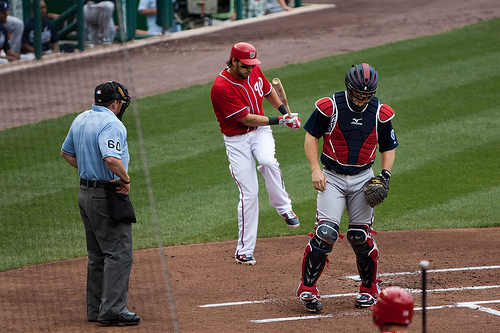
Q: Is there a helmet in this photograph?
A: Yes, there is a helmet.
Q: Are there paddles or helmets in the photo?
A: Yes, there is a helmet.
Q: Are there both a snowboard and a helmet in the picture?
A: No, there is a helmet but no snowboards.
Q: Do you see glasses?
A: No, there are no glasses.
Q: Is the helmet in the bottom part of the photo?
A: No, the helmet is in the top of the image.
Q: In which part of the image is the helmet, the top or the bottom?
A: The helmet is in the top of the image.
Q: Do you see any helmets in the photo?
A: Yes, there is a helmet.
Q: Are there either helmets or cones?
A: Yes, there is a helmet.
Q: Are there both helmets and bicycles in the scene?
A: No, there is a helmet but no bicycles.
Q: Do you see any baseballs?
A: No, there are no baseballs.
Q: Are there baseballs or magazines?
A: No, there are no baseballs or magazines.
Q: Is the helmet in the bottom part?
A: No, the helmet is in the top of the image.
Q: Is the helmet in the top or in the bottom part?
A: The helmet is in the top of the image.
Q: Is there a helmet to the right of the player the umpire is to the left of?
A: Yes, there is a helmet to the right of the player.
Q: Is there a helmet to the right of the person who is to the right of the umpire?
A: Yes, there is a helmet to the right of the player.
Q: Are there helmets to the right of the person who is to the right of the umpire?
A: Yes, there is a helmet to the right of the player.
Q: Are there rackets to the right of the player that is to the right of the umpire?
A: No, there is a helmet to the right of the player.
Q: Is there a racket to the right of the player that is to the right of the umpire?
A: No, there is a helmet to the right of the player.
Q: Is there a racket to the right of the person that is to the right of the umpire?
A: No, there is a helmet to the right of the player.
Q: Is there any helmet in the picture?
A: Yes, there is a helmet.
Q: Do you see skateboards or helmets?
A: Yes, there is a helmet.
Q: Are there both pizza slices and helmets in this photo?
A: No, there is a helmet but no pizza slices.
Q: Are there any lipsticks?
A: No, there are no lipsticks.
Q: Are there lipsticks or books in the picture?
A: No, there are no lipsticks or books.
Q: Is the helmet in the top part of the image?
A: Yes, the helmet is in the top of the image.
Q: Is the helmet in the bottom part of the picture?
A: No, the helmet is in the top of the image.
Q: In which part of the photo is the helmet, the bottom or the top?
A: The helmet is in the top of the image.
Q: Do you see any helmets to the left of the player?
A: Yes, there is a helmet to the left of the player.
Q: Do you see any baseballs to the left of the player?
A: No, there is a helmet to the left of the player.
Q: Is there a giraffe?
A: No, there are no giraffes.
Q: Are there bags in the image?
A: No, there are no bags.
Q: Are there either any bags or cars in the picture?
A: No, there are no bags or cars.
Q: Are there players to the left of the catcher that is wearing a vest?
A: Yes, there is a player to the left of the catcher.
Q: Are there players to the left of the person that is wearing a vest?
A: Yes, there is a player to the left of the catcher.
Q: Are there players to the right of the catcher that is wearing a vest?
A: No, the player is to the left of the catcher.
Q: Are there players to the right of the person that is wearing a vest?
A: No, the player is to the left of the catcher.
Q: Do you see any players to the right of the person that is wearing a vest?
A: No, the player is to the left of the catcher.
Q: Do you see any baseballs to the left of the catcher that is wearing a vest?
A: No, there is a player to the left of the catcher.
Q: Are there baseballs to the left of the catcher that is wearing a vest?
A: No, there is a player to the left of the catcher.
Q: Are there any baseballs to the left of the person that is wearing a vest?
A: No, there is a player to the left of the catcher.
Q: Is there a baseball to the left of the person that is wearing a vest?
A: No, there is a player to the left of the catcher.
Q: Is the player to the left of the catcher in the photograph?
A: Yes, the player is to the left of the catcher.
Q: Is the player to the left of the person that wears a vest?
A: Yes, the player is to the left of the catcher.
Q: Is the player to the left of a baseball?
A: No, the player is to the left of the catcher.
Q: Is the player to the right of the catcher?
A: No, the player is to the left of the catcher.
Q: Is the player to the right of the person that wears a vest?
A: No, the player is to the left of the catcher.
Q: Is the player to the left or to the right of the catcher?
A: The player is to the left of the catcher.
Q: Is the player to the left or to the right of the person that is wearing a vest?
A: The player is to the left of the catcher.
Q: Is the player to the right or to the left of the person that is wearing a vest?
A: The player is to the left of the catcher.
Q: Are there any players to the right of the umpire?
A: Yes, there is a player to the right of the umpire.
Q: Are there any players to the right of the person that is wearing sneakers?
A: Yes, there is a player to the right of the umpire.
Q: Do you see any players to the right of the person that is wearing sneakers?
A: Yes, there is a player to the right of the umpire.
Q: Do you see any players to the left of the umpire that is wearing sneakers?
A: No, the player is to the right of the umpire.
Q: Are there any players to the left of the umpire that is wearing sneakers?
A: No, the player is to the right of the umpire.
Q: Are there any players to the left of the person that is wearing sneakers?
A: No, the player is to the right of the umpire.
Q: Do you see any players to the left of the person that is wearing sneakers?
A: No, the player is to the right of the umpire.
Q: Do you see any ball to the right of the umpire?
A: No, there is a player to the right of the umpire.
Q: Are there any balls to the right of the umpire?
A: No, there is a player to the right of the umpire.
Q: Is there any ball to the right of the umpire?
A: No, there is a player to the right of the umpire.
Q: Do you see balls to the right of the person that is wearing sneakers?
A: No, there is a player to the right of the umpire.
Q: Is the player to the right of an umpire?
A: Yes, the player is to the right of an umpire.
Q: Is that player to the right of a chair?
A: No, the player is to the right of an umpire.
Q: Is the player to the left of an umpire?
A: No, the player is to the right of an umpire.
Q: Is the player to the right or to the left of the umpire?
A: The player is to the right of the umpire.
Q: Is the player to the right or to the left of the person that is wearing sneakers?
A: The player is to the right of the umpire.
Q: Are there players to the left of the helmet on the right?
A: Yes, there is a player to the left of the helmet.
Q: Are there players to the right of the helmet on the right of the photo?
A: No, the player is to the left of the helmet.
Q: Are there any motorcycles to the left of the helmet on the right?
A: No, there is a player to the left of the helmet.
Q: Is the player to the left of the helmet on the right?
A: Yes, the player is to the left of the helmet.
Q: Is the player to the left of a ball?
A: No, the player is to the left of the helmet.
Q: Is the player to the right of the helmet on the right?
A: No, the player is to the left of the helmet.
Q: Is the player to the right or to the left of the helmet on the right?
A: The player is to the left of the helmet.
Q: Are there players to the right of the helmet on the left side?
A: Yes, there is a player to the right of the helmet.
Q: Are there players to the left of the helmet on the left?
A: No, the player is to the right of the helmet.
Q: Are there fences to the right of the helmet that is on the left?
A: No, there is a player to the right of the helmet.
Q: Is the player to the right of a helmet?
A: Yes, the player is to the right of a helmet.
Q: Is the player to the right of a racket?
A: No, the player is to the right of a helmet.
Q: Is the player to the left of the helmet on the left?
A: No, the player is to the right of the helmet.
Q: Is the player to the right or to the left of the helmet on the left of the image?
A: The player is to the right of the helmet.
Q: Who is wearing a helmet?
A: The player is wearing a helmet.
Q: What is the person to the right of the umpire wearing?
A: The player is wearing a helmet.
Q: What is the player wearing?
A: The player is wearing a helmet.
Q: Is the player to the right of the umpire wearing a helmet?
A: Yes, the player is wearing a helmet.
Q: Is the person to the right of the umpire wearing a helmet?
A: Yes, the player is wearing a helmet.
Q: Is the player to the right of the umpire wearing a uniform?
A: No, the player is wearing a helmet.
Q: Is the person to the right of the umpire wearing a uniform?
A: No, the player is wearing a helmet.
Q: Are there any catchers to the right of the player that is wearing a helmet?
A: Yes, there is a catcher to the right of the player.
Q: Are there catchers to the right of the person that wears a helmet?
A: Yes, there is a catcher to the right of the player.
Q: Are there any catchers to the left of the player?
A: No, the catcher is to the right of the player.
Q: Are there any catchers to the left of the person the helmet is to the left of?
A: No, the catcher is to the right of the player.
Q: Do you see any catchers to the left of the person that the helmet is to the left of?
A: No, the catcher is to the right of the player.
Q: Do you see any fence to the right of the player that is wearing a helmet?
A: No, there is a catcher to the right of the player.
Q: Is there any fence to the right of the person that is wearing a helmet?
A: No, there is a catcher to the right of the player.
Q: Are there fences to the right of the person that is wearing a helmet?
A: No, there is a catcher to the right of the player.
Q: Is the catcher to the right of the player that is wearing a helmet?
A: Yes, the catcher is to the right of the player.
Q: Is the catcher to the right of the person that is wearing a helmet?
A: Yes, the catcher is to the right of the player.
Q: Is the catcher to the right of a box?
A: No, the catcher is to the right of the player.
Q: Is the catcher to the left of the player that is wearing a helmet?
A: No, the catcher is to the right of the player.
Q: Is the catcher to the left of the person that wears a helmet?
A: No, the catcher is to the right of the player.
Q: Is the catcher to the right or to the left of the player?
A: The catcher is to the right of the player.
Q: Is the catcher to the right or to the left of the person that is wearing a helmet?
A: The catcher is to the right of the player.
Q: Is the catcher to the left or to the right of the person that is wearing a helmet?
A: The catcher is to the right of the player.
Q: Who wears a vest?
A: The catcher wears a vest.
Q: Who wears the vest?
A: The catcher wears a vest.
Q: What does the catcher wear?
A: The catcher wears a vest.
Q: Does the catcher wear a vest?
A: Yes, the catcher wears a vest.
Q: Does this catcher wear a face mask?
A: No, the catcher wears a vest.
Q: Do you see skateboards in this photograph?
A: No, there are no skateboards.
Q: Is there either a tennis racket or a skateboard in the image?
A: No, there are no skateboards or rackets.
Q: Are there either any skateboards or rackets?
A: No, there are no skateboards or rackets.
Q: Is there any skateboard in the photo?
A: No, there are no skateboards.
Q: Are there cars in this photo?
A: No, there are no cars.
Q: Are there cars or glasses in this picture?
A: No, there are no cars or glasses.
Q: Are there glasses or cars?
A: No, there are no cars or glasses.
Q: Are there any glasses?
A: No, there are no glasses.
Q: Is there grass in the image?
A: Yes, there is grass.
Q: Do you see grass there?
A: Yes, there is grass.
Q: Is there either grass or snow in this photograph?
A: Yes, there is grass.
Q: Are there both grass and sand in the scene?
A: No, there is grass but no sand.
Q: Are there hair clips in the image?
A: No, there are no hair clips.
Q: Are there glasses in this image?
A: No, there are no glasses.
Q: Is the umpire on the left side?
A: Yes, the umpire is on the left of the image.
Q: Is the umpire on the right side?
A: No, the umpire is on the left of the image.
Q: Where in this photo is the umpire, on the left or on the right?
A: The umpire is on the left of the image.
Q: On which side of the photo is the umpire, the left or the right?
A: The umpire is on the left of the image.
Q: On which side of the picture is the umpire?
A: The umpire is on the left of the image.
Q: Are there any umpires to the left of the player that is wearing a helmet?
A: Yes, there is an umpire to the left of the player.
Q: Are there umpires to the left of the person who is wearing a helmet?
A: Yes, there is an umpire to the left of the player.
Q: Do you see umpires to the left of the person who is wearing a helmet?
A: Yes, there is an umpire to the left of the player.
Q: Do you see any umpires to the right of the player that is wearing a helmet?
A: No, the umpire is to the left of the player.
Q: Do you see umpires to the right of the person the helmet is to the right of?
A: No, the umpire is to the left of the player.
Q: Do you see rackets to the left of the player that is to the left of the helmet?
A: No, there is an umpire to the left of the player.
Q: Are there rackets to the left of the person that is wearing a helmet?
A: No, there is an umpire to the left of the player.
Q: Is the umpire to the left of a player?
A: Yes, the umpire is to the left of a player.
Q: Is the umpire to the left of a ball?
A: No, the umpire is to the left of a player.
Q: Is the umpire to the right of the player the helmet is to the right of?
A: No, the umpire is to the left of the player.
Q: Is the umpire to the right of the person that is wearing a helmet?
A: No, the umpire is to the left of the player.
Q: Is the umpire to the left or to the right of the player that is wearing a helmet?
A: The umpire is to the left of the player.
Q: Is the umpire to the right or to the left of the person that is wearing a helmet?
A: The umpire is to the left of the player.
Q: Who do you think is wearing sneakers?
A: The umpire is wearing sneakers.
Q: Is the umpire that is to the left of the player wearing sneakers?
A: Yes, the umpire is wearing sneakers.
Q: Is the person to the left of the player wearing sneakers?
A: Yes, the umpire is wearing sneakers.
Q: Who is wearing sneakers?
A: The umpire is wearing sneakers.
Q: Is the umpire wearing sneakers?
A: Yes, the umpire is wearing sneakers.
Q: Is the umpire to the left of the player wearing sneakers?
A: Yes, the umpire is wearing sneakers.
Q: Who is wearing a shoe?
A: The umpire is wearing a shoe.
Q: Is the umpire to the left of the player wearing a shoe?
A: Yes, the umpire is wearing a shoe.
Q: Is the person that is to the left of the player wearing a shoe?
A: Yes, the umpire is wearing a shoe.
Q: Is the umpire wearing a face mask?
A: No, the umpire is wearing a shoe.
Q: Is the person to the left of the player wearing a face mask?
A: No, the umpire is wearing a shoe.